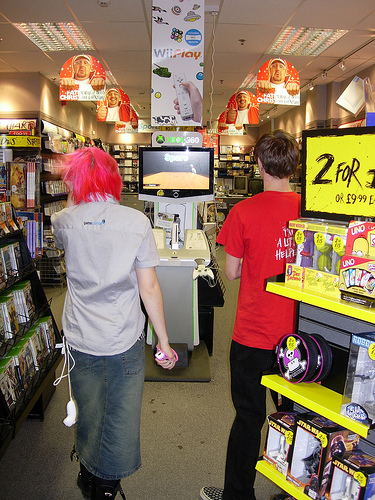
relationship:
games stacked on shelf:
[3, 227, 69, 443] [275, 262, 326, 388]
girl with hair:
[46, 144, 173, 498] [61, 146, 125, 203]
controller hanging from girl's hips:
[56, 332, 79, 429] [52, 323, 138, 351]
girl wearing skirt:
[49, 144, 177, 500] [64, 341, 148, 484]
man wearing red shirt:
[200, 125, 288, 498] [214, 189, 296, 353]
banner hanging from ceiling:
[124, 9, 227, 129] [12, 28, 152, 123]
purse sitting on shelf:
[273, 331, 318, 382] [265, 273, 374, 326]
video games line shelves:
[0, 211, 64, 426] [0, 142, 74, 420]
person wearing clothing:
[45, 145, 184, 498] [46, 186, 169, 484]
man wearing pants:
[200, 125, 302, 497] [212, 314, 278, 491]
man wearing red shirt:
[200, 125, 302, 497] [221, 189, 296, 349]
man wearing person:
[200, 125, 302, 497] [217, 133, 298, 349]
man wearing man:
[200, 125, 302, 497] [200, 125, 302, 497]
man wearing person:
[200, 125, 302, 497] [220, 133, 288, 440]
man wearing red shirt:
[200, 125, 302, 497] [215, 189, 300, 349]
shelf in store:
[254, 354, 374, 440] [2, 3, 371, 499]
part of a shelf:
[301, 390, 325, 406] [257, 365, 374, 443]